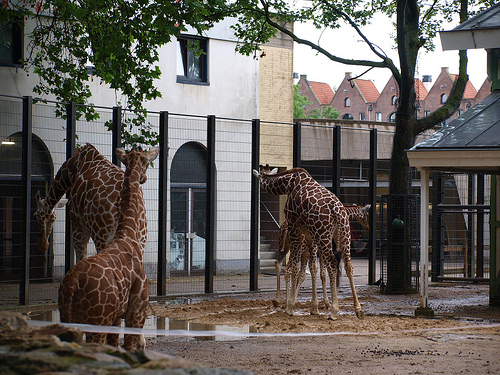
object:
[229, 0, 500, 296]
tree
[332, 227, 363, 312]
leg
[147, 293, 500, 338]
muddy area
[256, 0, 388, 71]
branches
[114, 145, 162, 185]
head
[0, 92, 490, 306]
fence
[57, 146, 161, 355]
giraffe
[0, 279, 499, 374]
dirt terrain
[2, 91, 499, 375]
enclosure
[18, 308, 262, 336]
puddle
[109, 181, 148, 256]
neck